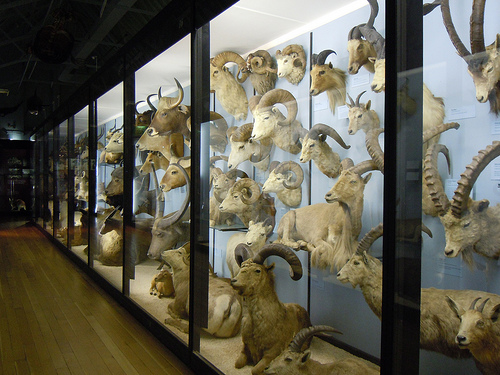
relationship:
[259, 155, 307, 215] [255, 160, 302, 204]
sheep has head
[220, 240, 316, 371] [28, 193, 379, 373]
ram seated on floor